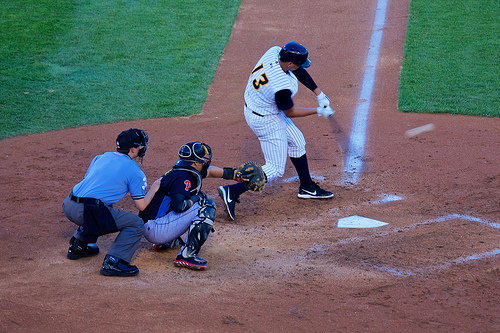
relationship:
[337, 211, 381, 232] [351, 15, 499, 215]
plate on top of diamond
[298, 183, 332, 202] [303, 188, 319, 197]
shoe with swish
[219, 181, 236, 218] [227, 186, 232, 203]
shoe with swish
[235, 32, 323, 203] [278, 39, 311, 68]
player with helmet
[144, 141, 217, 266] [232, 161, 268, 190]
catcher with mitt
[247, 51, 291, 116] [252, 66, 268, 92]
jersey with thirteen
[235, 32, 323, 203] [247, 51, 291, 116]
player with jersey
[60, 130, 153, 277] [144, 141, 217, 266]
umpire behind catcher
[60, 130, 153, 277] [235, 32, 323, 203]
umpire behind player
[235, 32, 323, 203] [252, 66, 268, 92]
player wearing thirteen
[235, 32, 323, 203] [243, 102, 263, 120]
player wearing belt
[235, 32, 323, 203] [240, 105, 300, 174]
player wearing pants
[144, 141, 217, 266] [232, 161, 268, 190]
catcher wearing mitt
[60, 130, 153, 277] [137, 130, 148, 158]
umpire wearing shield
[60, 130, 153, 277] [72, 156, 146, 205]
umpire wearing shirt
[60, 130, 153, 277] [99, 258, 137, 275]
umpire wearing shoe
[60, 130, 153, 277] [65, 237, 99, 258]
umpire wearing shoe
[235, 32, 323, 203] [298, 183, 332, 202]
player wearing shoe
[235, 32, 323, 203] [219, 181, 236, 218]
player wearing shoe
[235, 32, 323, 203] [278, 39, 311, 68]
player wearing helmet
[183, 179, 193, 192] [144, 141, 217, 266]
p on shoulder of catcher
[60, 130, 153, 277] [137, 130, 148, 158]
umpire with mask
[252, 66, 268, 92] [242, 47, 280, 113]
thirteen on players back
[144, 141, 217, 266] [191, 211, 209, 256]
catcher wearing guard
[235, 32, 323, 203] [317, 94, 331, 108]
player wearing glove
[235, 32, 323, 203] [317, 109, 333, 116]
player wearing glove